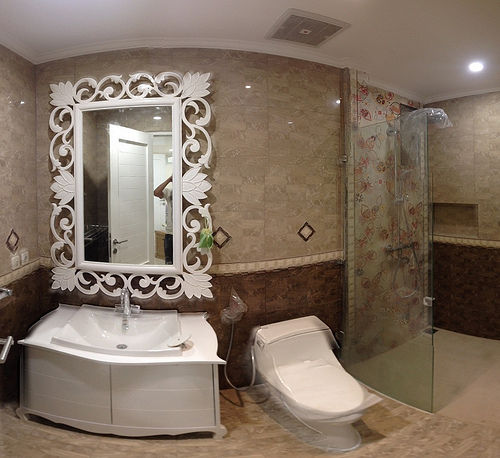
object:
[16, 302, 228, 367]
sink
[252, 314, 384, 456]
toilet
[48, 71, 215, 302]
mirror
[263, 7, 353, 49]
vent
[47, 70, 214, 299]
frame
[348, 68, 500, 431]
shower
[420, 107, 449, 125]
shower head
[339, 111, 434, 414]
partition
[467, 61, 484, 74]
light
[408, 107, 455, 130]
bag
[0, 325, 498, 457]
flooring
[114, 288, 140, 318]
faucet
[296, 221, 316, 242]
ornament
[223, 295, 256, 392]
cable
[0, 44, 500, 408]
wall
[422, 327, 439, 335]
object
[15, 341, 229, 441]
bottom part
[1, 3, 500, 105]
ceiling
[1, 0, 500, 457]
bathroom